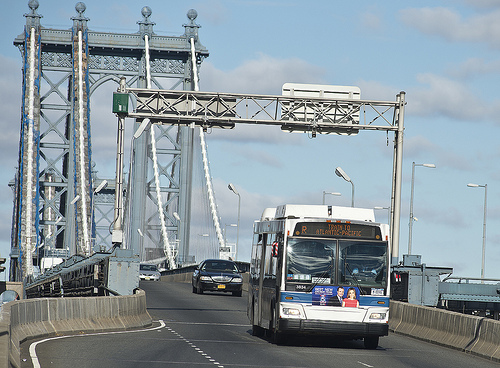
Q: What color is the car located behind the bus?
A: Black.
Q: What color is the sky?
A: Blue.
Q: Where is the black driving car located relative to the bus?
A: Behind.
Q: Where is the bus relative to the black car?
A: In front.